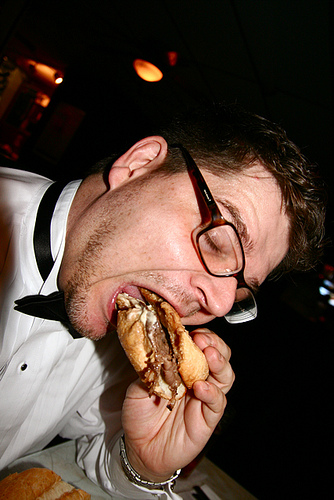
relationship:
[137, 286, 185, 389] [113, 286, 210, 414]
meat on bread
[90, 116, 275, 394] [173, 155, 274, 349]
man wearing glasses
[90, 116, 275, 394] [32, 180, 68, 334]
man wearing necktie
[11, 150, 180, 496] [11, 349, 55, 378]
shirt with button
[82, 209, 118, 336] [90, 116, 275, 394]
beard on face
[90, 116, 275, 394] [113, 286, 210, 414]
man biting bread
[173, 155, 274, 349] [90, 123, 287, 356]
glasses on face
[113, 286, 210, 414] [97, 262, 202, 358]
bread in mouth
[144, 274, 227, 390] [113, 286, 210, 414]
bread on bread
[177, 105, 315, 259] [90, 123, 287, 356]
hair on face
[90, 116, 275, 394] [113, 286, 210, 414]
man eating bread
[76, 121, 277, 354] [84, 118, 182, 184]
man's right ear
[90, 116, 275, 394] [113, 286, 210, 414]
man holding bread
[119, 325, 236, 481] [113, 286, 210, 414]
hand holding bread